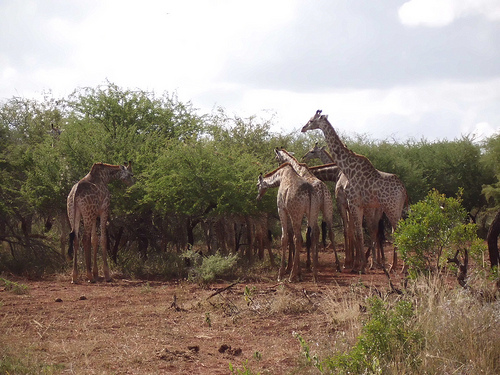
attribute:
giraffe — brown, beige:
[299, 93, 431, 280]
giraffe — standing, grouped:
[297, 104, 408, 277]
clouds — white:
[228, 17, 423, 120]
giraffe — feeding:
[49, 123, 173, 300]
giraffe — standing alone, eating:
[62, 156, 138, 291]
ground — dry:
[86, 272, 324, 336]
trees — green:
[101, 109, 263, 286]